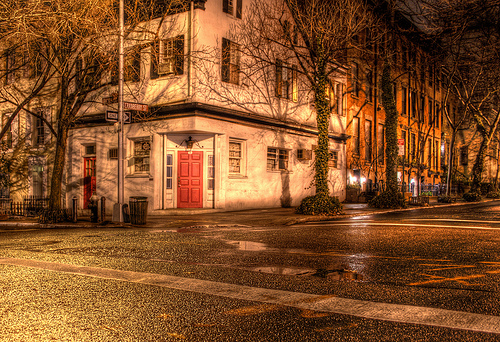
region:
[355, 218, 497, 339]
A grey lit road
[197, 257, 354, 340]
A grey lit road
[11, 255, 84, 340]
A grey lit road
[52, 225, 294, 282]
A grey lit road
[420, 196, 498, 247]
A grey lit road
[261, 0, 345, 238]
A tall leafless tree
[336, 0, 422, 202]
A tall leafless tree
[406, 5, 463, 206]
A tall leafless tree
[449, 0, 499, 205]
A tall leafless tree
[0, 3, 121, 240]
A tall leafless tree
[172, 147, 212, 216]
closed red door on building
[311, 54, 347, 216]
tree with green vines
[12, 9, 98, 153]
tree with no leaves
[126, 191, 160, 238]
black trash can on sidewalk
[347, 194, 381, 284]
glare of light on street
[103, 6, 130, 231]
pole on sidewalk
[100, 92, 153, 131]
three street signs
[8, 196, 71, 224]
black fence on sidewalk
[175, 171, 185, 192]
door knob on red door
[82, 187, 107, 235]
fire hydrant on sidewalk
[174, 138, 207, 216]
red doorway of building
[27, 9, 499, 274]
tall buildings across street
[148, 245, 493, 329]
white lines painted on road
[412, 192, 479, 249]
yellow lines painted on road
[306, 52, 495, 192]
line of trees by building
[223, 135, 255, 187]
window in white building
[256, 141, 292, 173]
window in white building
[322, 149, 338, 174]
window in white building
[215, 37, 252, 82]
window in white building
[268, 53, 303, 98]
window in white building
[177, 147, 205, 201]
Red door on apartment building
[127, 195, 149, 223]
Trash can near street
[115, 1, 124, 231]
Large gray metal pole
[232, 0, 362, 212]
Tall leafless tree in front of building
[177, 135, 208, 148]
Light above red door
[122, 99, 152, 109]
Red street sign on pole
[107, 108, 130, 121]
Black sign with white arrow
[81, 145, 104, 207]
Red door on side of building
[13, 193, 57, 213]
Low fence beside building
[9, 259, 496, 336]
White line marking crosswalk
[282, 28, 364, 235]
large tree on side walk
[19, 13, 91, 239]
large trees on the side walk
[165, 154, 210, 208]
red door on front of building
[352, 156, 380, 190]
lights on side of walk way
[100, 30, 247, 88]
windows on side of building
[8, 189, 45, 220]
black metal fence by building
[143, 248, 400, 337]
white painted line on street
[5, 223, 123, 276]
small puddles of water on the street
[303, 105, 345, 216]
leaves growing on side of tree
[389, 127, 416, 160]
red and white street sign